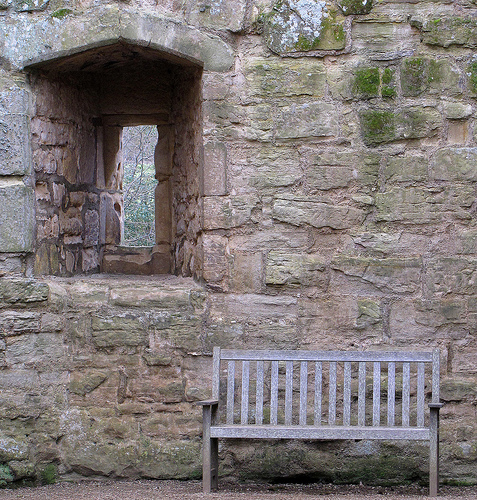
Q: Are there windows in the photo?
A: Yes, there is a window.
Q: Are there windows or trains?
A: Yes, there is a window.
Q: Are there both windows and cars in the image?
A: No, there is a window but no cars.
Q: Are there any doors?
A: No, there are no doors.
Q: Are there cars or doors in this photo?
A: No, there are no doors or cars.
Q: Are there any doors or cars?
A: No, there are no doors or cars.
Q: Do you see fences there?
A: No, there are no fences.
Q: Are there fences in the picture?
A: No, there are no fences.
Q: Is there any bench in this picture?
A: Yes, there is a bench.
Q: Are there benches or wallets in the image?
A: Yes, there is a bench.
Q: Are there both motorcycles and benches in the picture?
A: No, there is a bench but no motorcycles.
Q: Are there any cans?
A: No, there are no cans.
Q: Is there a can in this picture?
A: No, there are no cans.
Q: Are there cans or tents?
A: No, there are no cans or tents.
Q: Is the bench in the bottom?
A: Yes, the bench is in the bottom of the image.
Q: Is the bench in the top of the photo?
A: No, the bench is in the bottom of the image.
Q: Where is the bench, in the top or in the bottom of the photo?
A: The bench is in the bottom of the image.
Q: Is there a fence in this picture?
A: No, there are no fences.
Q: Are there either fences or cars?
A: No, there are no fences or cars.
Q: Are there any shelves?
A: No, there are no shelves.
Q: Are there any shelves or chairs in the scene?
A: No, there are no shelves or chairs.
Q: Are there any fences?
A: No, there are no fences.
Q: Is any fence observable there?
A: No, there are no fences.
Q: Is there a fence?
A: No, there are no fences.